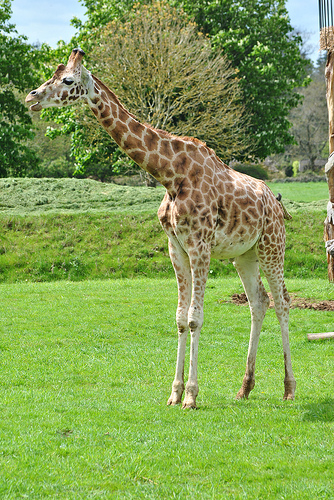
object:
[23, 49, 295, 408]
giraffe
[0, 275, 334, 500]
grass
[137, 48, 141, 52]
flower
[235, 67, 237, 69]
flower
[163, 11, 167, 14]
flower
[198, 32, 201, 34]
flower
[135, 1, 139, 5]
flower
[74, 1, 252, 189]
tree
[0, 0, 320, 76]
sky